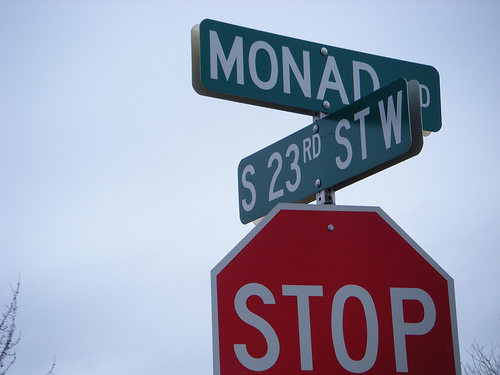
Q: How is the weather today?
A: It is cloudy.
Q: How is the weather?
A: It is cloudy.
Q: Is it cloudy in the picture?
A: Yes, it is cloudy.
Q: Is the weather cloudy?
A: Yes, it is cloudy.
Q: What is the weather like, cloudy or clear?
A: It is cloudy.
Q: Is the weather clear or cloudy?
A: It is cloudy.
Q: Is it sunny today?
A: No, it is cloudy.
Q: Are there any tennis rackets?
A: No, there are no tennis rackets.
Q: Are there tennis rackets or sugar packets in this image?
A: No, there are no tennis rackets or sugar packets.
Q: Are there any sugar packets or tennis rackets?
A: No, there are no tennis rackets or sugar packets.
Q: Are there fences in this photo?
A: No, there are no fences.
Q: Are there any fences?
A: No, there are no fences.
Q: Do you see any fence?
A: No, there are no fences.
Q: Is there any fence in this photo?
A: No, there are no fences.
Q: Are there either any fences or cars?
A: No, there are no fences or cars.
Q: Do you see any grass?
A: Yes, there is grass.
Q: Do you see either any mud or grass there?
A: Yes, there is grass.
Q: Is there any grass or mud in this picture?
A: Yes, there is grass.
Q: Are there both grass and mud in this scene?
A: No, there is grass but no mud.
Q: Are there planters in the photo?
A: No, there are no planters.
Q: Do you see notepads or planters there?
A: No, there are no planters or notepads.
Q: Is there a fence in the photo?
A: No, there are no fences.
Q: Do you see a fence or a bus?
A: No, there are no fences or buses.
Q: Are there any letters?
A: Yes, there are letters.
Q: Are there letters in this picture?
A: Yes, there are letters.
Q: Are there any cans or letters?
A: Yes, there are letters.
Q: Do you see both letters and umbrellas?
A: No, there are letters but no umbrellas.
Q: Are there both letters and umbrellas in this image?
A: No, there are letters but no umbrellas.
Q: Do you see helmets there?
A: No, there are no helmets.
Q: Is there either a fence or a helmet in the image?
A: No, there are no helmets or fences.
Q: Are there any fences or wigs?
A: No, there are no fences or wigs.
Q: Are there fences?
A: No, there are no fences.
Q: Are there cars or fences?
A: No, there are no fences or cars.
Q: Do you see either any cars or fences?
A: No, there are no fences or cars.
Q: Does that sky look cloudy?
A: Yes, the sky is cloudy.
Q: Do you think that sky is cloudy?
A: Yes, the sky is cloudy.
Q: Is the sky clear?
A: No, the sky is cloudy.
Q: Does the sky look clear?
A: No, the sky is cloudy.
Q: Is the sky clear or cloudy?
A: The sky is cloudy.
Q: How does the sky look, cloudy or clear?
A: The sky is cloudy.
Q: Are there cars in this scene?
A: No, there are no cars.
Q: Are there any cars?
A: No, there are no cars.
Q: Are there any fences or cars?
A: No, there are no cars or fences.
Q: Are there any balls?
A: No, there are no balls.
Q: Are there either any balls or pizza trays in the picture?
A: No, there are no balls or pizza trays.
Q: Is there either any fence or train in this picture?
A: No, there are no fences or trains.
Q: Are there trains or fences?
A: No, there are no fences or trains.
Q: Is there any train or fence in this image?
A: No, there are no fences or trains.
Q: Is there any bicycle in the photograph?
A: No, there are no bicycles.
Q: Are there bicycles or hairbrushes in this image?
A: No, there are no bicycles or hairbrushes.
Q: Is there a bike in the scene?
A: No, there are no bikes.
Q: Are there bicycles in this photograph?
A: No, there are no bicycles.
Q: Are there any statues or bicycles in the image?
A: No, there are no bicycles or statues.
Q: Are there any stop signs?
A: Yes, there is a stop sign.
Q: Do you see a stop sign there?
A: Yes, there is a stop sign.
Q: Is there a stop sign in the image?
A: Yes, there is a stop sign.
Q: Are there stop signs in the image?
A: Yes, there is a stop sign.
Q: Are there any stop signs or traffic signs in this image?
A: Yes, there is a stop sign.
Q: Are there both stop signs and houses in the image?
A: No, there is a stop sign but no houses.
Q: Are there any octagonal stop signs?
A: Yes, there is an octagonal stop sign.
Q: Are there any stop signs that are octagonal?
A: Yes, there is a stop sign that is octagonal.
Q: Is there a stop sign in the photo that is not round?
A: Yes, there is a octagonal stop sign.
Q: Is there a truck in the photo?
A: No, there are no trucks.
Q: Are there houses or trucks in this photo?
A: No, there are no trucks or houses.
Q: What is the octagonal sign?
A: The sign is a stop sign.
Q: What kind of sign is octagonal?
A: The sign is a stop sign.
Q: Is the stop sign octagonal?
A: Yes, the stop sign is octagonal.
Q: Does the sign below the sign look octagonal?
A: Yes, the stop sign is octagonal.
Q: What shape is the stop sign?
A: The stop sign is octagonal.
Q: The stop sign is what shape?
A: The stop sign is octagonal.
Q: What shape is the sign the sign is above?
A: The stop sign is octagonal.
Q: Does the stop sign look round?
A: No, the stop sign is octagonal.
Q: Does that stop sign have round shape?
A: No, the stop sign is octagonal.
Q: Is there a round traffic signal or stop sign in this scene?
A: No, there is a stop sign but it is octagonal.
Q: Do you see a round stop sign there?
A: No, there is a stop sign but it is octagonal.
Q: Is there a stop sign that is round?
A: No, there is a stop sign but it is octagonal.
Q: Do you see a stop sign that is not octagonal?
A: No, there is a stop sign but it is octagonal.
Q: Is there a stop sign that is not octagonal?
A: No, there is a stop sign but it is octagonal.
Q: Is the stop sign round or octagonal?
A: The stop sign is octagonal.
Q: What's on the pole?
A: The stop sign is on the pole.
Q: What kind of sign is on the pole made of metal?
A: The sign is a stop sign.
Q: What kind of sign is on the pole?
A: The sign is a stop sign.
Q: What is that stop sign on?
A: The stop sign is on the pole.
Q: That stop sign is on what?
A: The stop sign is on the pole.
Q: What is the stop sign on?
A: The stop sign is on the pole.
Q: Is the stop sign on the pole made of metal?
A: Yes, the stop sign is on the pole.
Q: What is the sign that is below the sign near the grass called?
A: The sign is a stop sign.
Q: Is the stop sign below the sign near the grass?
A: Yes, the stop sign is below the sign.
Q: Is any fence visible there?
A: No, there are no fences.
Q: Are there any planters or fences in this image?
A: No, there are no fences or planters.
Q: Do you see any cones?
A: No, there are no cones.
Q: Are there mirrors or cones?
A: No, there are no cones or mirrors.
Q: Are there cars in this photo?
A: No, there are no cars.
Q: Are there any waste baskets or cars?
A: No, there are no cars or waste baskets.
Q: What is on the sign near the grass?
A: The letter is on the sign.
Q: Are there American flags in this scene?
A: No, there are no American flags.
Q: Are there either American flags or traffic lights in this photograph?
A: No, there are no American flags or traffic lights.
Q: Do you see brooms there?
A: No, there are no brooms.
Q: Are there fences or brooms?
A: No, there are no brooms or fences.